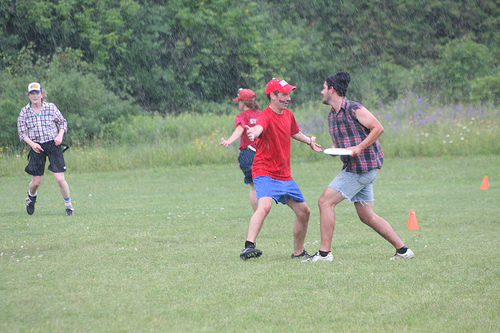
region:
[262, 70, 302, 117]
the head of a man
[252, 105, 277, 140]
the arm of a man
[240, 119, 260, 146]
the hand of a man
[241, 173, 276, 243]
the leg of a man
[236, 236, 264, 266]
a black shoe on the man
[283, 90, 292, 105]
the nose of a man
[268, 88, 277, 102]
the ear of a man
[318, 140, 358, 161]
a white plastic Frisbee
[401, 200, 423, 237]
an orange cone on the grass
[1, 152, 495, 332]
green grass on the ground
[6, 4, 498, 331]
the boys and a girl are playing in a park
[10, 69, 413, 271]
the group is playing frisbee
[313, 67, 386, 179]
the boy has a frisbee in his hand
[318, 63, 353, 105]
the man has a black knit cap on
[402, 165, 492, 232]
orange markers are on the field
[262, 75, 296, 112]
the boy has a red cap on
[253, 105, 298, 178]
the man is wearing a red t-shirt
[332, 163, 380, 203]
the man has blue jean cut offs on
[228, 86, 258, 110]
a girl has a red cap on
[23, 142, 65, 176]
the boy is wearing black shorts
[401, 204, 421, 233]
orange cone on grass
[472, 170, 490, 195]
orange cone on grass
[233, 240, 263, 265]
shoe on player's foot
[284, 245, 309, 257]
shoe on player's foot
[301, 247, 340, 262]
shoe on player's foot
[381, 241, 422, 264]
shoe on player's foot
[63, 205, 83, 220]
shoe on player's foot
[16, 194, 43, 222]
shoe on player's foot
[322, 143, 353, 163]
frisbee on player's hand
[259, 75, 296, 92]
red baseball cap on head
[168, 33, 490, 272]
People playing a sport.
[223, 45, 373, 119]
Man with a red hat.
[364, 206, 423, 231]
Orange cone on the field.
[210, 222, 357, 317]
Black tennis shoes on the man.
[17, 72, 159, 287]
Man in the background.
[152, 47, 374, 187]
Trees behind the field.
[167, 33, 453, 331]
Three people on the field.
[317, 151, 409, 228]
jean shorts on the man.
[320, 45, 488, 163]
Flowers by the tree.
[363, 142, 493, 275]
Two cones on the field.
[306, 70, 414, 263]
man holding frisbee in field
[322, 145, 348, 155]
white round frisbee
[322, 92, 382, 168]
sleeveless plaid shirt on man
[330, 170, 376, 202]
gray shorts on man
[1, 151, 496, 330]
large green grassy field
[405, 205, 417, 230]
small orange cone in field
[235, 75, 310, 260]
man blocking man with frisbee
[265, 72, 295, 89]
red baseball cap on man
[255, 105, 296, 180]
red tshirt on man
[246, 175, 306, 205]
blue shorts on man